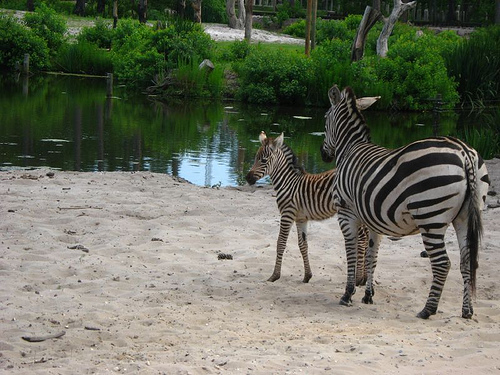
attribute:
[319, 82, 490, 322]
zebra — standing, striped, small, white, black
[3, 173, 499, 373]
ground — sandy, dirt, white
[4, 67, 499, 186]
water — dark, calm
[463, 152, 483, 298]
tail — long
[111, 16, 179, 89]
bush — green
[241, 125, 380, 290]
baby — brown, standing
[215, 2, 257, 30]
tree — small, brown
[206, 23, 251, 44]
sand — white